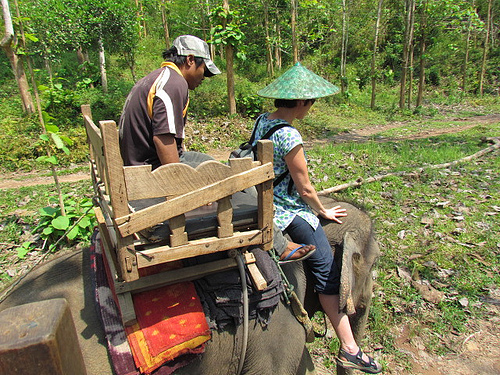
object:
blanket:
[92, 240, 214, 373]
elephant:
[0, 192, 382, 372]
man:
[119, 33, 317, 265]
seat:
[81, 103, 276, 283]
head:
[333, 208, 380, 318]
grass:
[1, 85, 498, 373]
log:
[332, 139, 500, 190]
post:
[5, 295, 70, 371]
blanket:
[195, 245, 282, 330]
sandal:
[279, 242, 318, 264]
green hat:
[256, 62, 338, 100]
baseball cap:
[171, 33, 225, 77]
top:
[251, 113, 321, 232]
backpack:
[220, 116, 298, 210]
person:
[250, 61, 384, 374]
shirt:
[118, 67, 190, 166]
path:
[0, 119, 478, 192]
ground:
[351, 186, 484, 195]